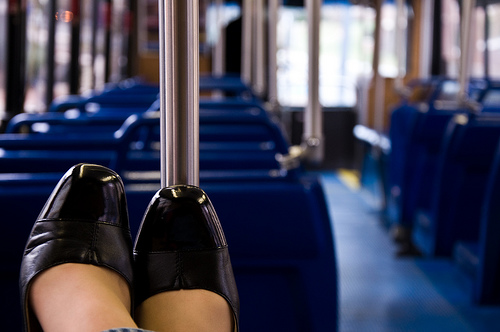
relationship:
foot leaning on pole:
[134, 182, 241, 326] [159, 0, 202, 185]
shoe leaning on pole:
[132, 183, 240, 331] [159, 0, 202, 185]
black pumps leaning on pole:
[22, 164, 132, 331] [157, 1, 204, 183]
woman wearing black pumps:
[12, 153, 253, 330] [26, 161, 238, 313]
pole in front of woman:
[159, 0, 202, 185] [16, 162, 243, 330]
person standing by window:
[214, 9, 261, 92] [271, 5, 374, 114]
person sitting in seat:
[224, 16, 241, 74] [383, 103, 463, 190]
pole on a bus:
[151, 11, 206, 187] [10, 2, 490, 329]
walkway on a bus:
[319, 170, 499, 330] [10, 2, 490, 329]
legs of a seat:
[391, 212, 423, 258] [383, 77, 484, 259]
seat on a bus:
[396, 107, 490, 241] [31, 0, 476, 285]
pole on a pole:
[151, 11, 206, 187] [303, 5, 324, 170]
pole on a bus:
[443, 17, 477, 99] [10, 2, 490, 329]